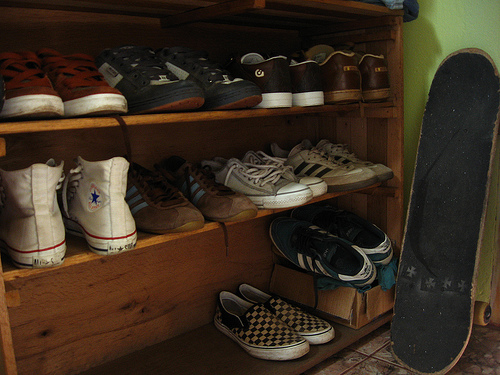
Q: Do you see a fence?
A: No, there are no fences.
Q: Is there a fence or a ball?
A: No, there are no fences or balls.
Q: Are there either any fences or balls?
A: No, there are no fences or balls.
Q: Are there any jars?
A: No, there are no jars.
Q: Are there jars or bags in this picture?
A: No, there are no jars or bags.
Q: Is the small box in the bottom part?
A: Yes, the box is in the bottom of the image.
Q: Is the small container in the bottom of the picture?
A: Yes, the box is in the bottom of the image.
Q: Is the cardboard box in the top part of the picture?
A: No, the box is in the bottom of the image.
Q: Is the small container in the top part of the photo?
A: No, the box is in the bottom of the image.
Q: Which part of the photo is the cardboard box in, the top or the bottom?
A: The box is in the bottom of the image.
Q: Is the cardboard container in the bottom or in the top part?
A: The box is in the bottom of the image.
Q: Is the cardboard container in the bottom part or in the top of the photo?
A: The box is in the bottom of the image.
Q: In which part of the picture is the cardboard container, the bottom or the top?
A: The box is in the bottom of the image.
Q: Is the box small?
A: Yes, the box is small.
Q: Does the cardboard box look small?
A: Yes, the box is small.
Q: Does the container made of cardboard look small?
A: Yes, the box is small.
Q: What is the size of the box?
A: The box is small.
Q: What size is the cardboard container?
A: The box is small.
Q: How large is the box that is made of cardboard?
A: The box is small.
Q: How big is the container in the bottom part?
A: The box is small.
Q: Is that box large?
A: No, the box is small.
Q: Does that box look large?
A: No, the box is small.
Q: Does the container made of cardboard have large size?
A: No, the box is small.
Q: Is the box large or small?
A: The box is small.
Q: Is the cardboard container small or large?
A: The box is small.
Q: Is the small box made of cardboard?
A: Yes, the box is made of cardboard.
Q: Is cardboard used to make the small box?
A: Yes, the box is made of cardboard.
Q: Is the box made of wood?
A: No, the box is made of cardboard.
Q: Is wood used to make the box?
A: No, the box is made of cardboard.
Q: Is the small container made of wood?
A: No, the box is made of cardboard.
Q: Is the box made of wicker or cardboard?
A: The box is made of cardboard.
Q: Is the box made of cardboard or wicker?
A: The box is made of cardboard.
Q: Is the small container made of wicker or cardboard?
A: The box is made of cardboard.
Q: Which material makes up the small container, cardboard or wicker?
A: The box is made of cardboard.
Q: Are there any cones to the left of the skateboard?
A: No, there is a box to the left of the skateboard.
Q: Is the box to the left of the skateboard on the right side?
A: Yes, the box is to the left of the skateboard.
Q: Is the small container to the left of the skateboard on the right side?
A: Yes, the box is to the left of the skateboard.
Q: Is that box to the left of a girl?
A: No, the box is to the left of the skateboard.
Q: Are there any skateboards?
A: Yes, there is a skateboard.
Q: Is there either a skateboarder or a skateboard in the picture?
A: Yes, there is a skateboard.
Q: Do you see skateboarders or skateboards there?
A: Yes, there is a skateboard.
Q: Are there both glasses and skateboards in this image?
A: No, there is a skateboard but no glasses.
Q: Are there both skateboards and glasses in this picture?
A: No, there is a skateboard but no glasses.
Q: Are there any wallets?
A: No, there are no wallets.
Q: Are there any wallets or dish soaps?
A: No, there are no wallets or dish soaps.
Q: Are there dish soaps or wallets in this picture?
A: No, there are no wallets or dish soaps.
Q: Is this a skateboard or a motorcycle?
A: This is a skateboard.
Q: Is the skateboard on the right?
A: Yes, the skateboard is on the right of the image.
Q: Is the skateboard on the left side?
A: No, the skateboard is on the right of the image.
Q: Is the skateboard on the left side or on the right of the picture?
A: The skateboard is on the right of the image.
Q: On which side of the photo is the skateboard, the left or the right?
A: The skateboard is on the right of the image.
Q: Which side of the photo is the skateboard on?
A: The skateboard is on the right of the image.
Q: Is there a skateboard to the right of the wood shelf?
A: Yes, there is a skateboard to the right of the shelf.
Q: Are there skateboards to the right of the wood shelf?
A: Yes, there is a skateboard to the right of the shelf.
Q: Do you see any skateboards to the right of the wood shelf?
A: Yes, there is a skateboard to the right of the shelf.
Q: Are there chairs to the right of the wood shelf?
A: No, there is a skateboard to the right of the shelf.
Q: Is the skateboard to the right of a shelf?
A: Yes, the skateboard is to the right of a shelf.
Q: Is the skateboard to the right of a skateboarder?
A: No, the skateboard is to the right of a shelf.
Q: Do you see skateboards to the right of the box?
A: Yes, there is a skateboard to the right of the box.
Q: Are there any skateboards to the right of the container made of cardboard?
A: Yes, there is a skateboard to the right of the box.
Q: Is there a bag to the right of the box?
A: No, there is a skateboard to the right of the box.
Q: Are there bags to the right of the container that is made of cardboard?
A: No, there is a skateboard to the right of the box.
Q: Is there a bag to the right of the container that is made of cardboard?
A: No, there is a skateboard to the right of the box.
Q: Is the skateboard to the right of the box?
A: Yes, the skateboard is to the right of the box.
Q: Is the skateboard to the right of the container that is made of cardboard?
A: Yes, the skateboard is to the right of the box.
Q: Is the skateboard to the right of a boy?
A: No, the skateboard is to the right of the box.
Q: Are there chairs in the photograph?
A: No, there are no chairs.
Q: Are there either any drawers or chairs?
A: No, there are no chairs or drawers.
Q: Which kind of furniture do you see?
A: The furniture is a shelf.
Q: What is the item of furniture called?
A: The piece of furniture is a shelf.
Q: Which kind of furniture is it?
A: The piece of furniture is a shelf.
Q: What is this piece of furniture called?
A: This is a shelf.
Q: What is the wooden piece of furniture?
A: The piece of furniture is a shelf.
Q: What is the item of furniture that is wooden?
A: The piece of furniture is a shelf.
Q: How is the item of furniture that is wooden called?
A: The piece of furniture is a shelf.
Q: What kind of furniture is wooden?
A: The furniture is a shelf.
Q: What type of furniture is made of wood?
A: The furniture is a shelf.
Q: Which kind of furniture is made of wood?
A: The furniture is a shelf.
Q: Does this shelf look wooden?
A: Yes, the shelf is wooden.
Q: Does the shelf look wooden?
A: Yes, the shelf is wooden.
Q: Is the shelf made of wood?
A: Yes, the shelf is made of wood.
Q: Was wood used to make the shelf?
A: Yes, the shelf is made of wood.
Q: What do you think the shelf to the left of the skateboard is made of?
A: The shelf is made of wood.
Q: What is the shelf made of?
A: The shelf is made of wood.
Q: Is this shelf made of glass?
A: No, the shelf is made of wood.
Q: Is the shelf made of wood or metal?
A: The shelf is made of wood.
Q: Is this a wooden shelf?
A: Yes, this is a wooden shelf.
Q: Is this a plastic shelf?
A: No, this is a wooden shelf.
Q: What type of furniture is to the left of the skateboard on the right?
A: The piece of furniture is a shelf.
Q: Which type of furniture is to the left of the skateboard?
A: The piece of furniture is a shelf.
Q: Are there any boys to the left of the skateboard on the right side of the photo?
A: No, there is a shelf to the left of the skateboard.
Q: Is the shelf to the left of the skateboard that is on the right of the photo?
A: Yes, the shelf is to the left of the skateboard.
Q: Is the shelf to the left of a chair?
A: No, the shelf is to the left of the skateboard.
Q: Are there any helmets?
A: No, there are no helmets.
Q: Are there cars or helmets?
A: No, there are no helmets or cars.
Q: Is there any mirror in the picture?
A: No, there are no mirrors.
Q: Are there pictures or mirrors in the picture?
A: No, there are no mirrors or pictures.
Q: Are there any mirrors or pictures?
A: No, there are no mirrors or pictures.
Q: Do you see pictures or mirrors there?
A: No, there are no mirrors or pictures.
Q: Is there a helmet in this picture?
A: No, there are no helmets.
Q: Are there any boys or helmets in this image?
A: No, there are no helmets or boys.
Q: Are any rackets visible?
A: No, there are no rackets.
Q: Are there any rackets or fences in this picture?
A: No, there are no rackets or fences.